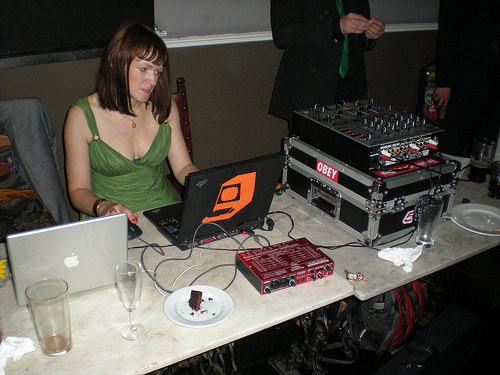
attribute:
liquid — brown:
[43, 329, 72, 353]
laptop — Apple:
[1, 203, 137, 299]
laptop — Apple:
[4, 206, 138, 309]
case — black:
[268, 106, 473, 249]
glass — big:
[21, 268, 79, 360]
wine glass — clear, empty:
[108, 256, 153, 342]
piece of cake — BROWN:
[179, 282, 215, 323]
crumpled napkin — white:
[375, 238, 427, 273]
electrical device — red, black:
[292, 93, 473, 235]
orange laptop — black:
[141, 151, 292, 240]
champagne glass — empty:
[112, 256, 153, 347]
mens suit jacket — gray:
[2, 96, 75, 228]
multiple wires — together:
[139, 222, 379, 299]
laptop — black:
[154, 151, 290, 249]